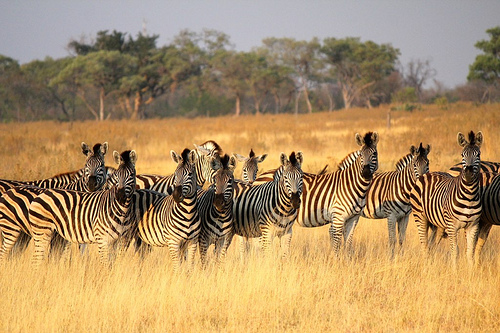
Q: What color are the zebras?
A: Black and white.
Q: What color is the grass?
A: Yellow.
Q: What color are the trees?
A: Green.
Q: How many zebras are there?
A: Thirteen.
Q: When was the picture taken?
A: Daytime.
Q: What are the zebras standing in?
A: Grass.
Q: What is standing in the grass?
A: Zebras.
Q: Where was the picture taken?
A: In the safari.